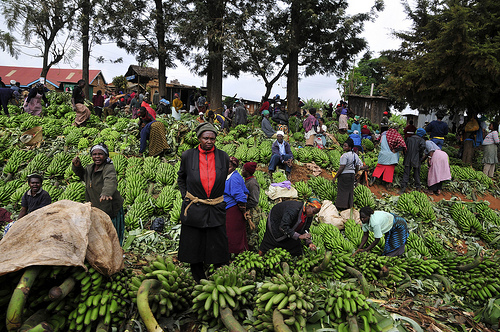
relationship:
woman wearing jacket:
[164, 119, 253, 266] [168, 140, 238, 266]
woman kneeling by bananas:
[353, 204, 408, 258] [324, 223, 354, 253]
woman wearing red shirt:
[164, 119, 253, 266] [197, 148, 214, 193]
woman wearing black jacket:
[164, 119, 253, 266] [175, 146, 231, 208]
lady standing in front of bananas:
[69, 137, 129, 207] [118, 159, 188, 270]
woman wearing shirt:
[164, 119, 253, 266] [198, 147, 217, 198]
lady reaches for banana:
[259, 188, 340, 278] [255, 240, 340, 313]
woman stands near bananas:
[164, 119, 253, 266] [182, 262, 259, 312]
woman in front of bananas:
[164, 119, 268, 269] [184, 236, 364, 304]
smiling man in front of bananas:
[12, 168, 55, 221] [3, 158, 95, 217]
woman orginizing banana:
[353, 204, 408, 258] [350, 296, 357, 313]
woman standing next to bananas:
[164, 119, 253, 266] [200, 263, 385, 330]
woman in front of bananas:
[72, 143, 122, 244] [1, 116, 176, 199]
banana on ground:
[350, 296, 357, 313] [0, 104, 497, 330]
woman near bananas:
[330, 131, 369, 208] [355, 182, 377, 207]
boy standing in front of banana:
[8, 162, 66, 217] [40, 217, 414, 319]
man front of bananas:
[265, 130, 297, 176] [293, 172, 335, 200]